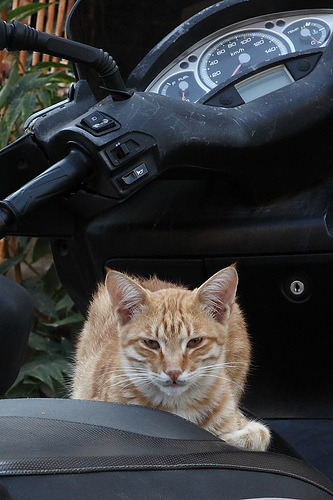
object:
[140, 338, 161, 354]
eye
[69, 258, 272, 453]
cat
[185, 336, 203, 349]
eye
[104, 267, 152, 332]
ear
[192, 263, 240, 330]
ear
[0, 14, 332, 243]
handle bar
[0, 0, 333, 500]
motorcycle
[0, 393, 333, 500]
seat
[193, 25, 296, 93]
speedometer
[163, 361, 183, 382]
nose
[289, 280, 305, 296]
key hole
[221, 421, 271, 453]
paw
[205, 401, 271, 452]
leg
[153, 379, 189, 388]
mouth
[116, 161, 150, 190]
horn button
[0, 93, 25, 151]
leaves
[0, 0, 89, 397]
plant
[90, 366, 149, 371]
whiskers